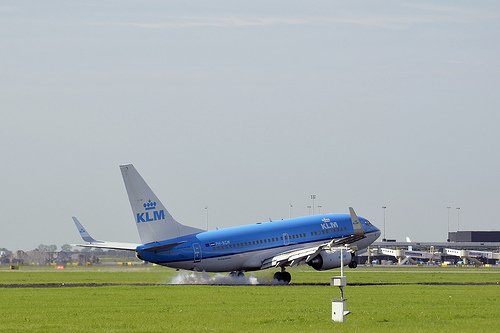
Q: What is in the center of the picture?
A: A blue and white plane.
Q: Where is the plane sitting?
A: In a field covered in green grass.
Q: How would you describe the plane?
A: Its blue and white.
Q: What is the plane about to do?
A: It is taking off.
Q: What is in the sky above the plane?
A: Whispy white clouds.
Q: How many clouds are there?
A: Very few clouds.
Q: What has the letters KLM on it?
A: A blue and white airplane.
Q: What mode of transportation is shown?
A: Planes.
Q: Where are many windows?
A: On the sides of the plane.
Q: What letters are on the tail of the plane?
A: KLM.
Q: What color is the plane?
A: Blue.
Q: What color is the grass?
A: Green.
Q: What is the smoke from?
A: Tires.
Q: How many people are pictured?
A: 0.